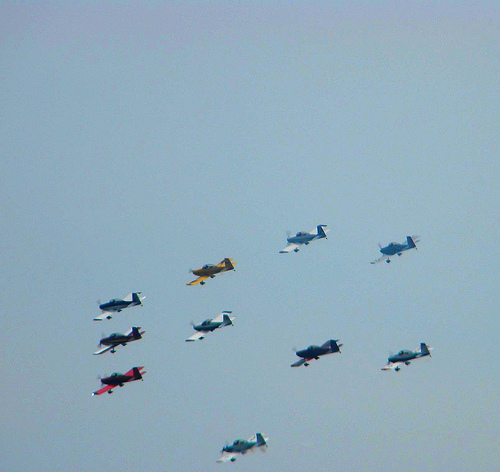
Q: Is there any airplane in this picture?
A: Yes, there is an airplane.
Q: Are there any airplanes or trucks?
A: Yes, there is an airplane.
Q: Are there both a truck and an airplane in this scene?
A: No, there is an airplane but no trucks.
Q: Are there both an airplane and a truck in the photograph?
A: No, there is an airplane but no trucks.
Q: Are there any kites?
A: No, there are no kites.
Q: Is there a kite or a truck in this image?
A: No, there are no kites or trucks.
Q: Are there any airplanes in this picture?
A: Yes, there is an airplane.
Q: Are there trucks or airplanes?
A: Yes, there is an airplane.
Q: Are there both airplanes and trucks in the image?
A: No, there is an airplane but no trucks.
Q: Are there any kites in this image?
A: No, there are no kites.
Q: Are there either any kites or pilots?
A: No, there are no kites or pilots.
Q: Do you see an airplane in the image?
A: Yes, there is an airplane.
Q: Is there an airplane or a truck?
A: Yes, there is an airplane.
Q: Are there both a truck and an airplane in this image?
A: No, there is an airplane but no trucks.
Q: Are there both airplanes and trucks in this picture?
A: No, there is an airplane but no trucks.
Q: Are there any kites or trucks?
A: No, there are no kites or trucks.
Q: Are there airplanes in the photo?
A: Yes, there is an airplane.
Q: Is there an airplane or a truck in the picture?
A: Yes, there is an airplane.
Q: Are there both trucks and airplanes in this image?
A: No, there is an airplane but no trucks.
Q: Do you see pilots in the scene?
A: No, there are no pilots.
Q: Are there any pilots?
A: No, there are no pilots.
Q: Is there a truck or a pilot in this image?
A: No, there are no pilots or trucks.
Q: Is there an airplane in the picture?
A: Yes, there is an airplane.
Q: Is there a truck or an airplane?
A: Yes, there is an airplane.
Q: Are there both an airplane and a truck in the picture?
A: No, there is an airplane but no trucks.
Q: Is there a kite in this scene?
A: No, there are no kites.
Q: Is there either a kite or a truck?
A: No, there are no kites or trucks.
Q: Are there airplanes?
A: Yes, there is an airplane.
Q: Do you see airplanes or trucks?
A: Yes, there is an airplane.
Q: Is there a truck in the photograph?
A: No, there are no trucks.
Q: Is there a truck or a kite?
A: No, there are no trucks or kites.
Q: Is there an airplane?
A: Yes, there is an airplane.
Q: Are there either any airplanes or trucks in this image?
A: Yes, there is an airplane.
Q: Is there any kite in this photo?
A: No, there are no kites.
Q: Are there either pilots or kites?
A: No, there are no kites or pilots.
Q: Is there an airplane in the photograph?
A: Yes, there is an airplane.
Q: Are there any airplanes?
A: Yes, there is an airplane.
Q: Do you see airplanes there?
A: Yes, there is an airplane.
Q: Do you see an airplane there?
A: Yes, there is an airplane.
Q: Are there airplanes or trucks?
A: Yes, there is an airplane.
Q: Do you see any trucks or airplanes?
A: Yes, there is an airplane.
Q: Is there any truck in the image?
A: No, there are no trucks.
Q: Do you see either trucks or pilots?
A: No, there are no trucks or pilots.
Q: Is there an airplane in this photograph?
A: Yes, there is an airplane.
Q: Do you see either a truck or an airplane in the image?
A: Yes, there is an airplane.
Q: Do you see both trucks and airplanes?
A: No, there is an airplane but no trucks.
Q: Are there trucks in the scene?
A: No, there are no trucks.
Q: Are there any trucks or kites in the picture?
A: No, there are no trucks or kites.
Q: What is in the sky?
A: The airplane is in the sky.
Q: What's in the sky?
A: The airplane is in the sky.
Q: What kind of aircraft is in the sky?
A: The aircraft is an airplane.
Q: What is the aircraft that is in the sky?
A: The aircraft is an airplane.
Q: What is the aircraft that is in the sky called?
A: The aircraft is an airplane.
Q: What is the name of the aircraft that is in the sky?
A: The aircraft is an airplane.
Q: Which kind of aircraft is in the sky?
A: The aircraft is an airplane.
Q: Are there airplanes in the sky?
A: Yes, there is an airplane in the sky.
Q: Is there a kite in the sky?
A: No, there is an airplane in the sky.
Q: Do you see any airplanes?
A: Yes, there is an airplane.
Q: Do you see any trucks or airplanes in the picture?
A: Yes, there is an airplane.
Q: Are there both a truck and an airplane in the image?
A: No, there is an airplane but no trucks.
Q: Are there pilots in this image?
A: No, there are no pilots.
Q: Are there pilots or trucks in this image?
A: No, there are no pilots or trucks.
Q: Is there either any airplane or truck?
A: Yes, there is an airplane.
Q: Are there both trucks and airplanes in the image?
A: No, there is an airplane but no trucks.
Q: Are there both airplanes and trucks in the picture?
A: No, there is an airplane but no trucks.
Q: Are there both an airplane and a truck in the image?
A: No, there is an airplane but no trucks.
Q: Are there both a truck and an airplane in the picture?
A: No, there is an airplane but no trucks.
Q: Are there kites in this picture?
A: No, there are no kites.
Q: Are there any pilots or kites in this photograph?
A: No, there are no kites or pilots.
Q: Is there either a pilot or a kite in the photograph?
A: No, there are no kites or pilots.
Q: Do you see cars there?
A: No, there are no cars.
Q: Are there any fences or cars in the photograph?
A: No, there are no cars or fences.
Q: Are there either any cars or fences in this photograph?
A: No, there are no cars or fences.